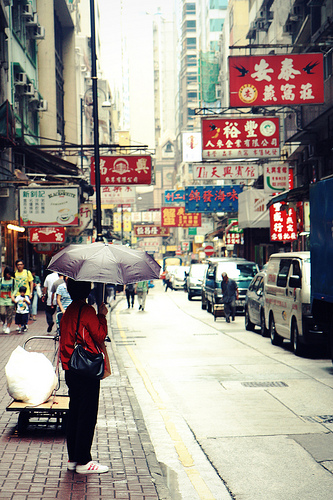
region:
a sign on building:
[219, 35, 328, 117]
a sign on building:
[196, 108, 281, 178]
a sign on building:
[181, 153, 273, 193]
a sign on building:
[176, 174, 239, 241]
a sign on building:
[153, 204, 211, 233]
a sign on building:
[82, 145, 156, 201]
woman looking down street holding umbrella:
[47, 243, 162, 482]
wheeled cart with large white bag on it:
[7, 333, 74, 426]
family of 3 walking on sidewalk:
[0, 260, 31, 337]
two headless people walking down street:
[122, 278, 149, 316]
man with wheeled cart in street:
[212, 270, 238, 325]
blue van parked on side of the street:
[200, 257, 258, 309]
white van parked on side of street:
[265, 250, 304, 349]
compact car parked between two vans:
[243, 271, 263, 332]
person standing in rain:
[14, 228, 202, 479]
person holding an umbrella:
[36, 212, 162, 486]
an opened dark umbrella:
[44, 204, 195, 356]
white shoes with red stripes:
[47, 445, 129, 482]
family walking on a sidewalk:
[2, 253, 44, 338]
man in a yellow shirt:
[13, 254, 40, 317]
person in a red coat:
[44, 271, 132, 388]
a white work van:
[260, 245, 319, 371]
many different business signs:
[160, 101, 306, 288]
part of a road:
[118, 281, 324, 495]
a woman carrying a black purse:
[44, 240, 161, 473]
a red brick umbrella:
[0, 307, 170, 498]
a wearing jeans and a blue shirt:
[218, 272, 242, 323]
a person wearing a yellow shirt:
[12, 258, 33, 311]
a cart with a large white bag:
[3, 335, 69, 432]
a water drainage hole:
[241, 379, 284, 388]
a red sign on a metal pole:
[29, 142, 152, 186]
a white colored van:
[264, 250, 311, 350]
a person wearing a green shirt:
[132, 279, 147, 311]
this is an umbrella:
[32, 219, 172, 307]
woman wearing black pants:
[54, 350, 102, 469]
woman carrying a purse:
[66, 301, 120, 383]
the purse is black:
[59, 303, 107, 383]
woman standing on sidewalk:
[18, 202, 219, 498]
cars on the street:
[149, 216, 325, 343]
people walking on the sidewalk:
[3, 216, 68, 347]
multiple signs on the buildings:
[58, 40, 323, 270]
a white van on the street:
[259, 238, 324, 359]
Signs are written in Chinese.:
[200, 110, 284, 163]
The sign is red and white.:
[198, 110, 285, 166]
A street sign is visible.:
[201, 244, 214, 257]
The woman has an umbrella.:
[44, 236, 164, 480]